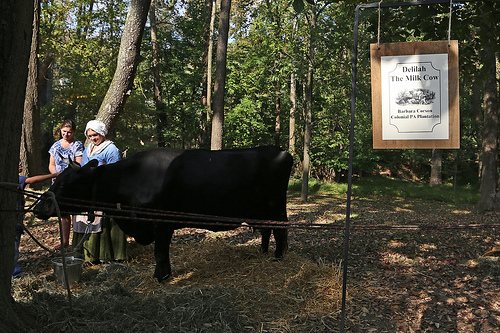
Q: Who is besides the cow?
A: Two women.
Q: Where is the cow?
A: On the grass.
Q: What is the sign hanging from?
A: Metal bar.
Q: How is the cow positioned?
A: Standing up.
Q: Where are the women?
A: By the cow.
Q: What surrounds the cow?
A: Trees.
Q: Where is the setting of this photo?
A: Woods.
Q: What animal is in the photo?
A: Cow.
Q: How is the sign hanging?
A: By rope.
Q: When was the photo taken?
A: In the daytime.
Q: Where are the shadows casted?
A: On the ground.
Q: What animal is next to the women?
A: A cow.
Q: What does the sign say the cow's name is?
A: Delilah.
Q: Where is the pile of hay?
A: Under the cow.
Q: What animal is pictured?
A: A cow.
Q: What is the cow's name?
A: Delilah.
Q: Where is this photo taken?
A: On a farm.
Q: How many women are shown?
A: Two.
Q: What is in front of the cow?
A: A bucket.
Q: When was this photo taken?
A: During the daytime.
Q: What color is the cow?
A: Black.